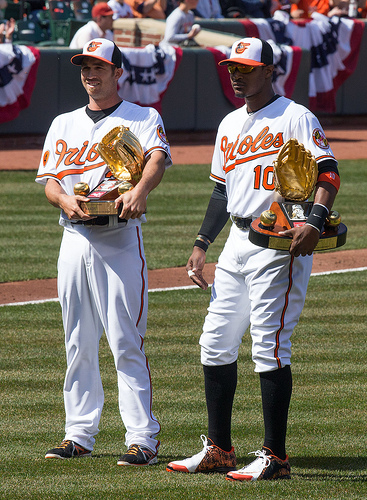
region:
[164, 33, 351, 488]
the guy is wearing a wrist band in his left hand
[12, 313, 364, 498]
green grasses are there in the field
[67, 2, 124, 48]
the person is sitting with red cap on his head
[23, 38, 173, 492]
the person is standing on the green grass field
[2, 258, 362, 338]
white marking on the green grass field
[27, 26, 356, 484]
two players are standing beside one another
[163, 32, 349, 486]
the person is wearing sun glasses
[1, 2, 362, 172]
people are sitting and watching the field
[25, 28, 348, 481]
two base ball players holding the trophies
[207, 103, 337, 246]
the number 10 is visible in the t-shirt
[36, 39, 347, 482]
two baseball player holding trophies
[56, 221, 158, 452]
man wearing white pants with a red line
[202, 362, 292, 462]
man wearing black long socks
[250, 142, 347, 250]
a trophy with a golden catcher's mitt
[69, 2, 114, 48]
a man sitting behind a green fence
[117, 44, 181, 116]
a white, red and blue decoration on a fence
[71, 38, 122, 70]
man wearing a cap on his head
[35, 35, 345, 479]
two men standing on a baseball field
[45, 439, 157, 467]
man wearing black sneakers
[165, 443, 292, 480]
man wearing white, orange and black sneakers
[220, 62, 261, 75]
glasses on man's face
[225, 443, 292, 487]
white and orange shoe on left foot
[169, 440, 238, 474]
white and orange shoe on right foot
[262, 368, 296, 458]
long black sock on left leg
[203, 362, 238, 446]
black sock on right leg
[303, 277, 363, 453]
green grass on the ground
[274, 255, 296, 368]
stripe on man's pants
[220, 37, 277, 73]
hat on the man's head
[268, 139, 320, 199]
the golden glove award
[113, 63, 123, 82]
the man's left ear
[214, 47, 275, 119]
player is wearing sunglasses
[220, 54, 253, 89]
player is wearing sunglasses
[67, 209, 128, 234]
the belt is black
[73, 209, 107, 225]
the belt is black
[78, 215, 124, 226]
the belt is black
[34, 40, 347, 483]
a couple of baseball players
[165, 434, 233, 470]
black white and orange shoe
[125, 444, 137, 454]
the laces are yellow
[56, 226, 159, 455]
the pants are white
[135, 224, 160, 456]
red stripe on pants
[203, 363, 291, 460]
the socks are black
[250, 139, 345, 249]
the trophy is large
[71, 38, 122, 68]
orange black and white hat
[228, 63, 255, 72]
the lenses are yellow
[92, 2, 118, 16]
the hat is orange